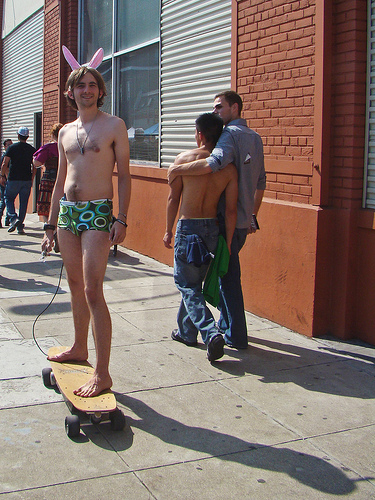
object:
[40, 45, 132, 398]
man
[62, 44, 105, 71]
bunny ears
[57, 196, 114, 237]
swimsuit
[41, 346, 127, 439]
skateboard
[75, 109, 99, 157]
necklace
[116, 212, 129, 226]
wristband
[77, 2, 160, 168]
window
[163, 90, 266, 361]
couple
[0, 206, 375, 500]
sidewalk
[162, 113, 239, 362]
man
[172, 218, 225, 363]
pants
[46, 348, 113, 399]
foot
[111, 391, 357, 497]
shadow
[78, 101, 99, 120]
neck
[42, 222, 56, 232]
watch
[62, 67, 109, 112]
hair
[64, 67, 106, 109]
head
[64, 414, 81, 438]
wheel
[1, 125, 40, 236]
person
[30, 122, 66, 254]
person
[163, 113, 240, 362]
person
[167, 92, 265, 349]
person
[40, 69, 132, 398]
person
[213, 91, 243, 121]
head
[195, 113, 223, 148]
head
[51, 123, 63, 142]
head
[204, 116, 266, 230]
shirt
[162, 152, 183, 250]
left arm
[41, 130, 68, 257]
right arm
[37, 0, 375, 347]
brick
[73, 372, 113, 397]
left foot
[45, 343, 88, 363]
right foot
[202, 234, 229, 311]
shirt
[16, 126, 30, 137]
hat